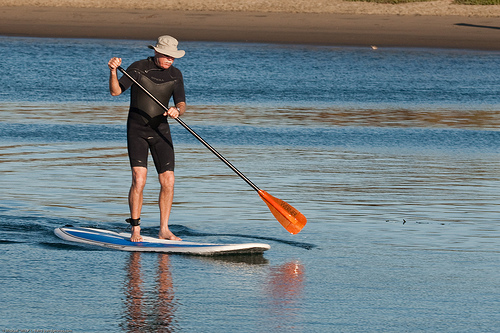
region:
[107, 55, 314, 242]
black water paddle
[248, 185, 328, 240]
wide orange portion of water paddle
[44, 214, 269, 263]
blue and white surfboard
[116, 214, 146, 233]
black tether strap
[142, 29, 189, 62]
grey hat on man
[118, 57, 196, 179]
black wet suit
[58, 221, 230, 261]
blue stripe on surfboard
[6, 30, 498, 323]
body of water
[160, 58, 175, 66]
white mustache on man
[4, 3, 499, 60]
sand shore at foot of water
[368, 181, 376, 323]
Assorted fruits in a box on the table.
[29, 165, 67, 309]
Assorted fruits in a box on the table.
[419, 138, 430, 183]
Assorted fruits in a box on the table.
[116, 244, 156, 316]
Assorted fruits in a box on the table.